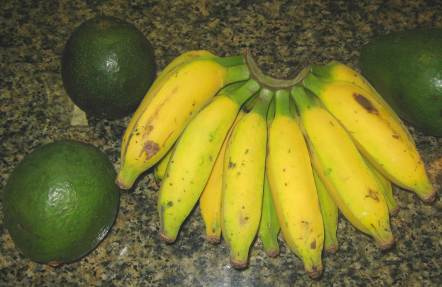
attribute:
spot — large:
[135, 121, 165, 162]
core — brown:
[244, 59, 308, 85]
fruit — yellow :
[124, 48, 430, 260]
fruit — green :
[350, 27, 440, 135]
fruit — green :
[54, 13, 170, 128]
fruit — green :
[3, 138, 121, 267]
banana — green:
[256, 173, 279, 258]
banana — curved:
[118, 23, 241, 187]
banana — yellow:
[312, 72, 437, 197]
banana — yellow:
[297, 107, 393, 254]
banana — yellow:
[260, 116, 334, 272]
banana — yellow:
[218, 102, 268, 265]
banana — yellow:
[156, 90, 231, 251]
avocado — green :
[0, 139, 123, 264]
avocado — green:
[63, 9, 150, 122]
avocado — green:
[9, 123, 168, 266]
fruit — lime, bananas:
[2, 0, 441, 281]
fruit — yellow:
[68, 17, 154, 124]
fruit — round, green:
[7, 116, 148, 275]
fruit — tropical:
[116, 45, 436, 278]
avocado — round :
[3, 128, 135, 266]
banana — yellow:
[105, 63, 236, 155]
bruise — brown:
[341, 91, 388, 133]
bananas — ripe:
[166, 50, 428, 261]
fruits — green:
[65, 20, 154, 114]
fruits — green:
[0, 136, 113, 265]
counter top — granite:
[3, 1, 61, 132]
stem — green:
[222, 41, 359, 97]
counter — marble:
[5, 3, 434, 284]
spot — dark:
[351, 88, 381, 120]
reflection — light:
[183, 251, 226, 285]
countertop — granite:
[102, 251, 215, 276]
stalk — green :
[216, 46, 339, 120]